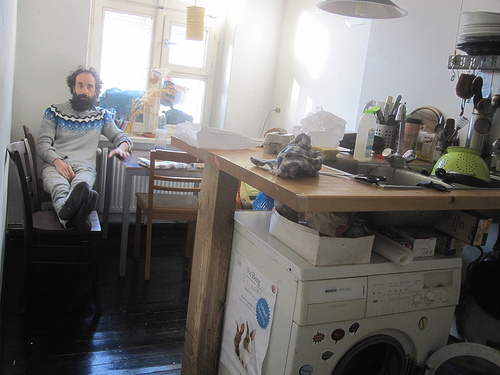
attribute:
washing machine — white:
[217, 207, 462, 373]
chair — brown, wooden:
[126, 129, 221, 273]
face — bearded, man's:
[71, 69, 99, 107]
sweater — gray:
[40, 104, 124, 181]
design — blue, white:
[46, 103, 116, 132]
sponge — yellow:
[309, 140, 344, 164]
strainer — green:
[434, 139, 491, 191]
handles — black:
[353, 168, 390, 189]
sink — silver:
[311, 146, 452, 190]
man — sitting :
[34, 66, 134, 239]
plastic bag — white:
[174, 116, 266, 156]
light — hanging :
[185, 4, 205, 41]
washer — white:
[228, 209, 498, 374]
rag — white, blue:
[253, 130, 321, 195]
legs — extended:
[39, 150, 99, 227]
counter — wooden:
[280, 177, 367, 212]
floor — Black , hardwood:
[10, 220, 199, 371]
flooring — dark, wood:
[7, 240, 190, 372]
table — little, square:
[113, 146, 215, 275]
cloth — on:
[245, 126, 328, 190]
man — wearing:
[35, 44, 132, 319]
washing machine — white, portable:
[214, 209, 499, 374]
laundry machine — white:
[241, 202, 467, 373]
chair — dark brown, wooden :
[6, 136, 106, 322]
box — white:
[269, 208, 379, 266]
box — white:
[391, 225, 437, 252]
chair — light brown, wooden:
[132, 144, 203, 276]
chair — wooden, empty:
[130, 130, 223, 286]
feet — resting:
[31, 180, 111, 242]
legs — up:
[44, 167, 104, 232]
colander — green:
[431, 144, 493, 184]